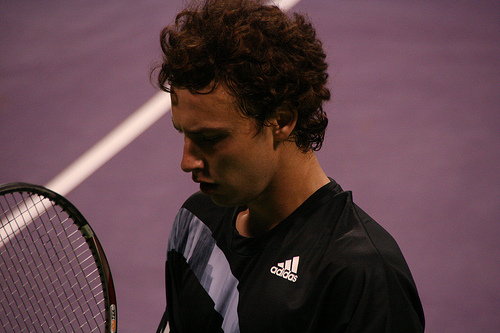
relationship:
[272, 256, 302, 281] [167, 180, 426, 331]
logo on shirt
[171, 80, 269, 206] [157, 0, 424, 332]
face on player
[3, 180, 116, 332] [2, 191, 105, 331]
racquet has strings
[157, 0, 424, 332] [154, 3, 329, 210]
man has head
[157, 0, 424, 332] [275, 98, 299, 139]
man has ear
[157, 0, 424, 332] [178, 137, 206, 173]
man has nose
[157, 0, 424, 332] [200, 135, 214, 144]
man has eye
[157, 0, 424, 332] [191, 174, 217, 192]
man has mouth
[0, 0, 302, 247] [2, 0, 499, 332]
stripe on court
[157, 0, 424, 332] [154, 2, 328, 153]
man has hair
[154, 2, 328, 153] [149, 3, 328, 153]
hair has perspiration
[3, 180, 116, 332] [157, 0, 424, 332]
racket in front of man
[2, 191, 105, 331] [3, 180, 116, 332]
strings are on raquet